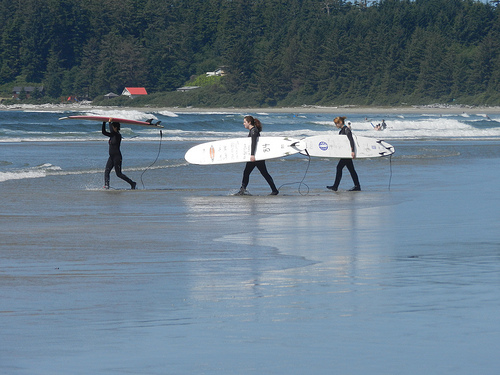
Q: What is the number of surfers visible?
A: 3.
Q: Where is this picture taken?
A: Beach.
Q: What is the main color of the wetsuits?
A: Black.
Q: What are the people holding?
A: Surfboards.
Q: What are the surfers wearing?
A: Wetsuits.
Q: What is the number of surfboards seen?
A: 3.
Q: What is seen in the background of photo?
A: Trees.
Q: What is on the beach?
A: Sand.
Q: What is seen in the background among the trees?
A: Buildings.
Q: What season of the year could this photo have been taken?
A: Summer.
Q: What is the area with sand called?
A: Beach.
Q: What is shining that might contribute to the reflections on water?
A: Sun.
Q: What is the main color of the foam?
A: White.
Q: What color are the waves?
A: White.